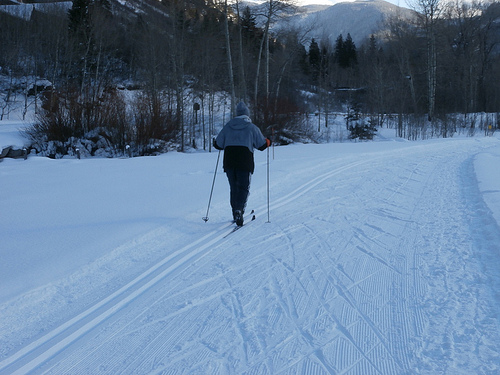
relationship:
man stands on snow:
[212, 101, 272, 228] [148, 197, 448, 314]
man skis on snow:
[212, 101, 272, 228] [1, 137, 494, 372]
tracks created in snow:
[0, 135, 499, 375] [1, 137, 494, 372]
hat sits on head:
[233, 99, 252, 116] [235, 105, 252, 117]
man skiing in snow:
[211, 102, 271, 228] [0, 68, 497, 372]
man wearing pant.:
[212, 101, 272, 228] [225, 169, 247, 213]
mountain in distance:
[216, 1, 449, 61] [1, 3, 463, 69]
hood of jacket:
[228, 112, 254, 131] [215, 110, 264, 175]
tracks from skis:
[0, 135, 499, 375] [218, 198, 263, 240]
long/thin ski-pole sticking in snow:
[263, 145, 272, 223] [1, 137, 494, 372]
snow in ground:
[23, 169, 463, 351] [3, 136, 470, 351]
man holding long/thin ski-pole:
[212, 101, 272, 228] [263, 145, 272, 223]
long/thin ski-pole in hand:
[263, 145, 272, 223] [259, 128, 275, 153]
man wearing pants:
[212, 101, 272, 228] [230, 173, 246, 208]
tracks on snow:
[96, 122, 412, 347] [1, 141, 443, 371]